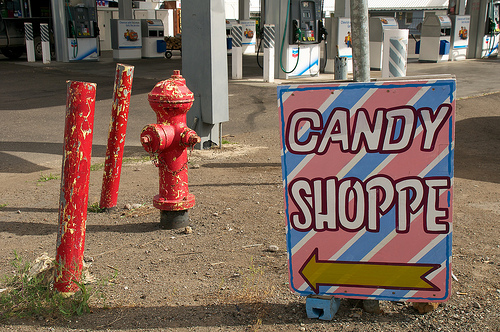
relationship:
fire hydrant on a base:
[141, 66, 205, 211] [160, 209, 189, 230]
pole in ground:
[55, 77, 95, 295] [134, 228, 260, 295]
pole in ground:
[99, 64, 134, 212] [134, 228, 260, 295]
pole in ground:
[99, 64, 134, 212] [201, 193, 282, 270]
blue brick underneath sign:
[306, 297, 341, 321] [279, 80, 456, 300]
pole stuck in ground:
[55, 77, 95, 295] [1, 59, 496, 330]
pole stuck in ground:
[105, 62, 131, 206] [140, 247, 265, 292]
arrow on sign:
[292, 248, 446, 294] [279, 80, 456, 300]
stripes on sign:
[333, 236, 379, 264] [274, 69, 465, 308]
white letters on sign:
[284, 104, 458, 152] [279, 80, 456, 300]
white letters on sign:
[283, 175, 451, 232] [279, 80, 456, 300]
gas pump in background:
[263, 0, 323, 89] [5, 10, 490, 172]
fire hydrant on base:
[140, 70, 201, 230] [158, 205, 191, 232]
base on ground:
[160, 209, 189, 230] [138, 222, 267, 315]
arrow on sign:
[298, 247, 441, 295] [231, 27, 477, 329]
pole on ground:
[55, 77, 95, 295] [1, 59, 496, 330]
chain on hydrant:
[150, 156, 191, 171] [142, 68, 197, 229]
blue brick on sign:
[304, 294, 348, 322] [279, 80, 456, 300]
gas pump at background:
[258, 0, 319, 80] [0, 0, 500, 150]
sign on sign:
[277, 75, 459, 303] [274, 69, 465, 308]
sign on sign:
[277, 75, 459, 303] [219, 42, 474, 308]